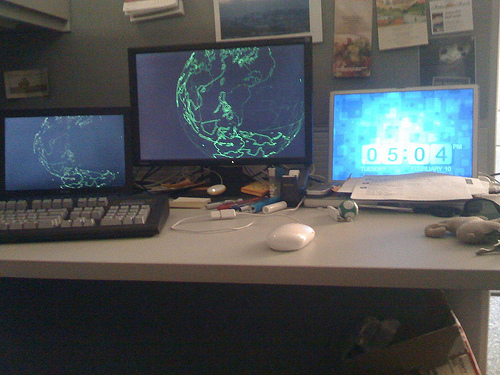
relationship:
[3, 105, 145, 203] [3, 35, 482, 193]
monitor in row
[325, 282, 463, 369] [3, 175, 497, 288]
box under desk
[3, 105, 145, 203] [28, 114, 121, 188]
monitor displays globe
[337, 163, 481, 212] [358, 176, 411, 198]
paper has printing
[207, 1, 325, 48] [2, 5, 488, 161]
picture on wall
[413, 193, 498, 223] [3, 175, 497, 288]
sunglasses are on desk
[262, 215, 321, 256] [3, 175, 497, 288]
mouse on desk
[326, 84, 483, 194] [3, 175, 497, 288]
computer sits on desk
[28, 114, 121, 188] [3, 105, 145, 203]
globe on monitor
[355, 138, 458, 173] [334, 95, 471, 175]
time on screen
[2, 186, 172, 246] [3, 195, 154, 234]
keyboard has keys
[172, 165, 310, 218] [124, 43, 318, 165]
junk under monitor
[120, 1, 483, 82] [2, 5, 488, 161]
papers posted to wall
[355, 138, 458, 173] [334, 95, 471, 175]
time showing on screen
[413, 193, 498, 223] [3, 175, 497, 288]
sunglasses lay on desk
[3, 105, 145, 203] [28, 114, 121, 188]
monitor shows globe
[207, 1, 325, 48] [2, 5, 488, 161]
picture tacked to wall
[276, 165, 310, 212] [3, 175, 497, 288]
tape dispenser on desk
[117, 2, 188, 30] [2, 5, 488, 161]
bent paper on wall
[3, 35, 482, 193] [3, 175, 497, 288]
row on desk